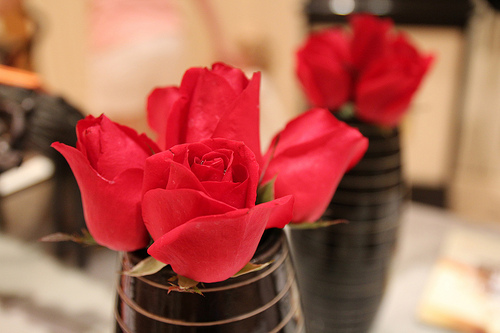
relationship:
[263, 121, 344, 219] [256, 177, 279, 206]
flower on stem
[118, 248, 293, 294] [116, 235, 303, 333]
lines around vase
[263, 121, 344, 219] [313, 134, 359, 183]
flower has petal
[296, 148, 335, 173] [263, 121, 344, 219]
groove in flower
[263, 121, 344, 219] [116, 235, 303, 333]
flower inside vase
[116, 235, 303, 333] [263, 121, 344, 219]
vase holding flower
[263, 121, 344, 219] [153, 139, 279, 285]
flower next to flower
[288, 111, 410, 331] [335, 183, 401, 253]
vase has lines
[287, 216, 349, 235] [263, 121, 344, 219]
leaf attached to flower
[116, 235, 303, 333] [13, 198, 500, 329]
vase on top of table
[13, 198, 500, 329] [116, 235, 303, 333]
table holding vase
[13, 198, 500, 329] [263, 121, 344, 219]
table holding flower